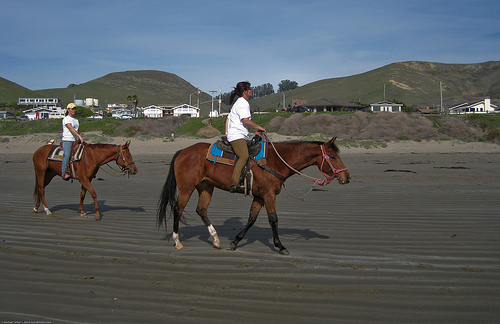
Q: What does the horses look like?
A: Brown.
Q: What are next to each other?
A: Two horses.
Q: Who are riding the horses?
A: Two people.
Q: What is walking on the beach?
A: The horses.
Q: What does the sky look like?
A: It is blue with a few clouds.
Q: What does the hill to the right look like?
A: Green with a few brown spots.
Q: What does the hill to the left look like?
A: Green with a brown line near the top.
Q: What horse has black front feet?
A: The horse in front.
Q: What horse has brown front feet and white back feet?
A: The horse in back.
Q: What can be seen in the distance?
A: A number of hills.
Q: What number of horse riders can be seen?
A: Two.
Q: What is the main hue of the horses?
A: Brown.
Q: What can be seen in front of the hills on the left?
A: A number of houses.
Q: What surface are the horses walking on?
A: Sand.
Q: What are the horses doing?
A: Walking on the beach.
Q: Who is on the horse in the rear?
A: A woman.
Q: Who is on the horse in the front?
A: A man.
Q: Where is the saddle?
A: On the horse.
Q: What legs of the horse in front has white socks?
A: The two back legs.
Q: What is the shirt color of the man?
A: White.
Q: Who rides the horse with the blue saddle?
A: A man.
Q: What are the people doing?
A: Riding a horse.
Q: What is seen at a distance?
A: Green hills.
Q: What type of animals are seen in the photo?
A: Horses.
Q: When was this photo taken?
A: Daytime.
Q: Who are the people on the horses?
A: Women.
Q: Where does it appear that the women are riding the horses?
A: On beach.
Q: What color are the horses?
A: Brown.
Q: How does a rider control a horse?
A: With reins.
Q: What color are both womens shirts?
A: White.